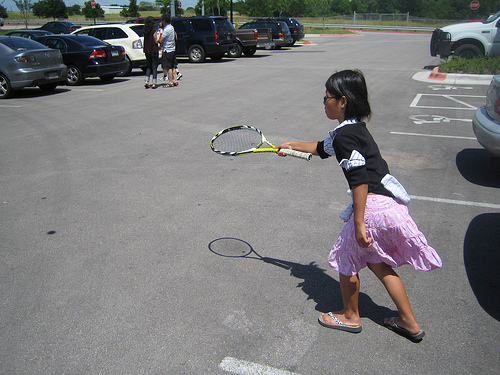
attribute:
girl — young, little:
[272, 67, 445, 343]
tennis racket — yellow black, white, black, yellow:
[208, 122, 316, 164]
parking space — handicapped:
[385, 105, 484, 135]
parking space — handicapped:
[420, 81, 495, 98]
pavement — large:
[1, 30, 499, 374]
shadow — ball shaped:
[42, 228, 59, 237]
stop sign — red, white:
[89, 1, 97, 10]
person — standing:
[141, 19, 159, 90]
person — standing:
[157, 21, 184, 80]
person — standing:
[157, 14, 177, 89]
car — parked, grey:
[1, 33, 69, 98]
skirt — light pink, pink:
[324, 190, 442, 279]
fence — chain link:
[285, 12, 453, 29]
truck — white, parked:
[427, 7, 499, 70]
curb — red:
[428, 64, 445, 82]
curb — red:
[318, 31, 355, 38]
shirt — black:
[310, 116, 398, 199]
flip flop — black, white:
[382, 314, 426, 340]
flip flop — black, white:
[314, 311, 368, 334]